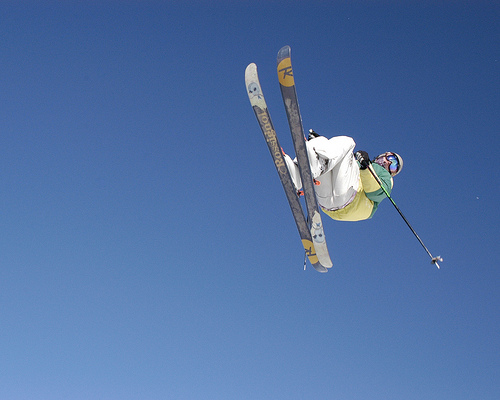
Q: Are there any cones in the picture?
A: No, there are no cones.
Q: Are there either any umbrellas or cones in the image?
A: No, there are no cones or umbrellas.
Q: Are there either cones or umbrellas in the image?
A: No, there are no cones or umbrellas.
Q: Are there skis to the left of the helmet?
A: Yes, there is a ski to the left of the helmet.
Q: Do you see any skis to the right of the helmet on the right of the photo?
A: No, the ski is to the left of the helmet.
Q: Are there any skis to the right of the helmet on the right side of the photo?
A: No, the ski is to the left of the helmet.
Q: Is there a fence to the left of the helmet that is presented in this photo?
A: No, there is a ski to the left of the helmet.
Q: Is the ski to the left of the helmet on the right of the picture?
A: Yes, the ski is to the left of the helmet.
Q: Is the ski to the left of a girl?
A: No, the ski is to the left of the helmet.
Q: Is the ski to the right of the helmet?
A: No, the ski is to the left of the helmet.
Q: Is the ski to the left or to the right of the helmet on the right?
A: The ski is to the left of the helmet.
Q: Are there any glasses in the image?
A: No, there are no glasses.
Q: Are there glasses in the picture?
A: No, there are no glasses.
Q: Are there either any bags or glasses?
A: No, there are no glasses or bags.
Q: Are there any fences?
A: No, there are no fences.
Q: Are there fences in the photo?
A: No, there are no fences.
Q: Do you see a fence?
A: No, there are no fences.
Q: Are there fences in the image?
A: No, there are no fences.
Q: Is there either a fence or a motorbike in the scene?
A: No, there are no fences or motorcycles.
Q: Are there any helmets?
A: Yes, there is a helmet.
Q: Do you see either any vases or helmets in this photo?
A: Yes, there is a helmet.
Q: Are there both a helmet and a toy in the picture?
A: No, there is a helmet but no toys.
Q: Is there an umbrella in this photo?
A: No, there are no umbrellas.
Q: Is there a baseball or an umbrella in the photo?
A: No, there are no umbrellas or baseballs.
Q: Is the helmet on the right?
A: Yes, the helmet is on the right of the image.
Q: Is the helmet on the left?
A: No, the helmet is on the right of the image.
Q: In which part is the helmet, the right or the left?
A: The helmet is on the right of the image.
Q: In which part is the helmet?
A: The helmet is on the right of the image.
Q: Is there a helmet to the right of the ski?
A: Yes, there is a helmet to the right of the ski.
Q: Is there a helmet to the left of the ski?
A: No, the helmet is to the right of the ski.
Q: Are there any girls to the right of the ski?
A: No, there is a helmet to the right of the ski.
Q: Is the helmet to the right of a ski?
A: Yes, the helmet is to the right of a ski.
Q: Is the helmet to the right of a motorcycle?
A: No, the helmet is to the right of a ski.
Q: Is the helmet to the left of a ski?
A: No, the helmet is to the right of a ski.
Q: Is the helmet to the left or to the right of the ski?
A: The helmet is to the right of the ski.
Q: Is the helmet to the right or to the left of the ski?
A: The helmet is to the right of the ski.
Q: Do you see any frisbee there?
A: No, there are no frisbees.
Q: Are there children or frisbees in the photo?
A: No, there are no frisbees or children.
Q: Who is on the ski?
A: The alien is on the ski.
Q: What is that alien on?
A: The alien is on the ski.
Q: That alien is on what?
A: The alien is on the ski.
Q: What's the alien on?
A: The alien is on the ski.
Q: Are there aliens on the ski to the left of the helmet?
A: Yes, there is an alien on the ski.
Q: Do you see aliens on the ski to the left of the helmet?
A: Yes, there is an alien on the ski.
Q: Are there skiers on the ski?
A: No, there is an alien on the ski.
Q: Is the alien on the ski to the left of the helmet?
A: Yes, the alien is on the ski.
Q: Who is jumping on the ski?
A: The alien is jumping on the ski.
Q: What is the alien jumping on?
A: The alien is jumping on the ski.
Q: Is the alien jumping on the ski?
A: Yes, the alien is jumping on the ski.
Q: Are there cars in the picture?
A: No, there are no cars.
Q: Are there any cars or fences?
A: No, there are no cars or fences.